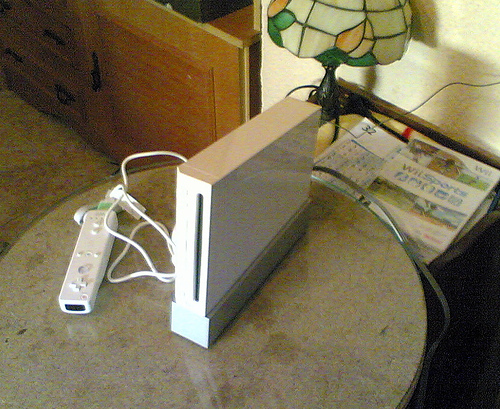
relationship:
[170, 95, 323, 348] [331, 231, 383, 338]
console on table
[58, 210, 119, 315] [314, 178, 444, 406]
controller on table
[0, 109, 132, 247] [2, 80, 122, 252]
carpet on floor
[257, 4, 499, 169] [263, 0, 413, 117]
wall behind lamp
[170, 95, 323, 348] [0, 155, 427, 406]
console on table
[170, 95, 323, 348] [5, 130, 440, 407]
console on table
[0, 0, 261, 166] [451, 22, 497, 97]
cabinets next to wall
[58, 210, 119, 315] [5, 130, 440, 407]
controller on table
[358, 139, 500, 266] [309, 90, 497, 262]
book on table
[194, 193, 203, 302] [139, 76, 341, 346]
disk slit on console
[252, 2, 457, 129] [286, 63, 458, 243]
lamp on table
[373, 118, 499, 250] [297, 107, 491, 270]
book on table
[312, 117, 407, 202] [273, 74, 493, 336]
book on chair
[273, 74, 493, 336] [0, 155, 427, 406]
chair next to table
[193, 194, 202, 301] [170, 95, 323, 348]
disk slit on console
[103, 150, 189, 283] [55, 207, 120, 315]
cord on controller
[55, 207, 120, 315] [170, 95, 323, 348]
controller on console